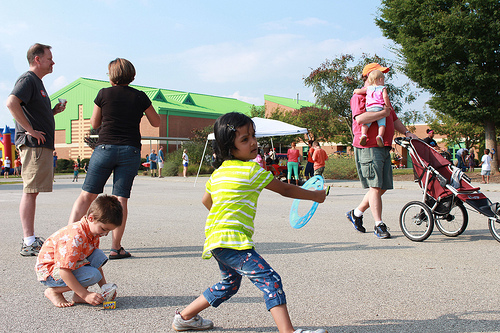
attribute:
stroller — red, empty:
[393, 132, 499, 250]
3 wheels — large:
[394, 196, 499, 244]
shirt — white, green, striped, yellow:
[193, 156, 279, 258]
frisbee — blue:
[285, 167, 328, 231]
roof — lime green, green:
[144, 88, 317, 111]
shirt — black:
[92, 84, 152, 148]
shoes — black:
[337, 209, 394, 241]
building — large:
[137, 83, 330, 133]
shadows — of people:
[275, 234, 491, 330]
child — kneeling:
[30, 189, 124, 316]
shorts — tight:
[80, 144, 141, 200]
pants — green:
[352, 145, 398, 192]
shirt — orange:
[28, 216, 106, 277]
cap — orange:
[357, 59, 394, 76]